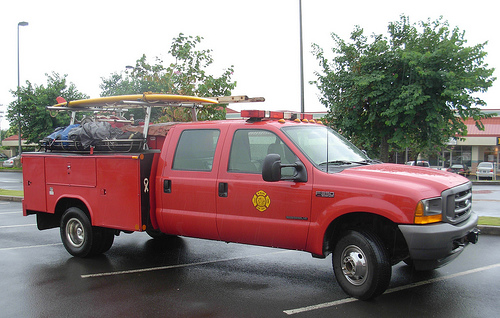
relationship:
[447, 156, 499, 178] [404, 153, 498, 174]
vehicles parked in background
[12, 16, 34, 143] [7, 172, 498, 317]
pole near parking lot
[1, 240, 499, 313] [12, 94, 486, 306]
pavement under truck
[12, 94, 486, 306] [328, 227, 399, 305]
truck has tire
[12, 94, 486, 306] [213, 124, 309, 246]
truck has door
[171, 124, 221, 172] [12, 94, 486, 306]
window on truck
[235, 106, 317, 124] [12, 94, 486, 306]
lights on top truck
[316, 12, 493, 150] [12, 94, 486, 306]
tree behind truck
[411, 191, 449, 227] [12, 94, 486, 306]
headlight on truck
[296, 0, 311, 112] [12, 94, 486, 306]
post behind truck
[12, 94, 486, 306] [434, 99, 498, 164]
car parked front building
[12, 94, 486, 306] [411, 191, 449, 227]
truck has light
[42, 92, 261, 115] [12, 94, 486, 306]
grill son truck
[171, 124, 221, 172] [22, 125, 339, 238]
window on side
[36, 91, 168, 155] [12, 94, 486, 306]
cargo back of truck